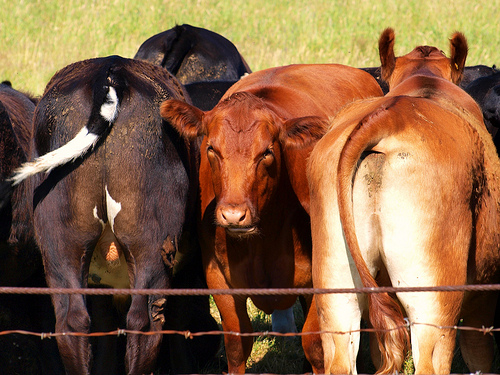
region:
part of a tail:
[382, 289, 409, 315]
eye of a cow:
[263, 159, 268, 174]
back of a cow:
[128, 206, 136, 216]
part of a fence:
[266, 335, 287, 360]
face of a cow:
[233, 142, 248, 165]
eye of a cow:
[266, 151, 271, 158]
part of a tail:
[381, 309, 392, 318]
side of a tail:
[363, 244, 366, 251]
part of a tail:
[365, 320, 382, 322]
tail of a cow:
[369, 328, 404, 329]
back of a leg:
[336, 323, 347, 340]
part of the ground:
[260, 323, 282, 355]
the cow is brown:
[189, 43, 327, 302]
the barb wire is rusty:
[0, 315, 235, 358]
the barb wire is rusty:
[211, 316, 498, 343]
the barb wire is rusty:
[8, 319, 499, 357]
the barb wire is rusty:
[2, 272, 498, 339]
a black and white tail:
[29, 80, 149, 217]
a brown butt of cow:
[313, 80, 470, 290]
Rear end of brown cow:
[312, 26, 499, 371]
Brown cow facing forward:
[158, 61, 379, 372]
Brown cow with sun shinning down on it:
[160, 88, 325, 240]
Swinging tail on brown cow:
[342, 106, 417, 373]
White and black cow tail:
[4, 66, 136, 182]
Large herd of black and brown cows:
[0, 21, 496, 370]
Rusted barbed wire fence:
[0, 323, 495, 340]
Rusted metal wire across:
[0, 277, 497, 294]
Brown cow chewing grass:
[211, 196, 272, 239]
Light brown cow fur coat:
[158, 61, 385, 373]